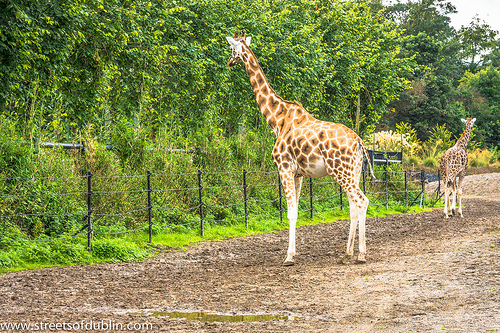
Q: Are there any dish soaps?
A: No, there are no dish soaps.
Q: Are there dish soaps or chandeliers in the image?
A: No, there are no dish soaps or chandeliers.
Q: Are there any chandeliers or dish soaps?
A: No, there are no dish soaps or chandeliers.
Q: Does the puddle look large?
A: Yes, the puddle is large.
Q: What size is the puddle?
A: The puddle is large.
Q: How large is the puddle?
A: The puddle is large.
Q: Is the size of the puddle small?
A: No, the puddle is large.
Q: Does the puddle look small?
A: No, the puddle is large.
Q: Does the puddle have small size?
A: No, the puddle is large.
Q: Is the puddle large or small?
A: The puddle is large.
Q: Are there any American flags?
A: No, there are no American flags.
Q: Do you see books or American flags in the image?
A: No, there are no American flags or books.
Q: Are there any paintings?
A: No, there are no paintings.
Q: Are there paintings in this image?
A: No, there are no paintings.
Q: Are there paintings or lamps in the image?
A: No, there are no paintings or lamps.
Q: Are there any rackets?
A: No, there are no rackets.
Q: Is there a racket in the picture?
A: No, there are no rackets.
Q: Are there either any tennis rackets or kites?
A: No, there are no tennis rackets or kites.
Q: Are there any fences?
A: Yes, there is a fence.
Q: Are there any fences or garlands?
A: Yes, there is a fence.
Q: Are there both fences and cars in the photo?
A: No, there is a fence but no cars.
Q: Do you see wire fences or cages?
A: Yes, there is a wire fence.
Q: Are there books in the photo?
A: No, there are no books.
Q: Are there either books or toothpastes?
A: No, there are no books or toothpastes.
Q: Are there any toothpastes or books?
A: No, there are no books or toothpastes.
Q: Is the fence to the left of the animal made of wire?
A: Yes, the fence is made of wire.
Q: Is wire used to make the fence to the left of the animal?
A: Yes, the fence is made of wire.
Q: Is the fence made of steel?
A: No, the fence is made of wire.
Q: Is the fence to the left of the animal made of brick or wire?
A: The fence is made of wire.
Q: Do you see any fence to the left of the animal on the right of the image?
A: Yes, there is a fence to the left of the animal.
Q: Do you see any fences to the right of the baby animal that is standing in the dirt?
A: No, the fence is to the left of the animal.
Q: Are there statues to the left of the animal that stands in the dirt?
A: No, there is a fence to the left of the animal.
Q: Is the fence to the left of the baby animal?
A: Yes, the fence is to the left of the animal.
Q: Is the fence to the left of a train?
A: No, the fence is to the left of the animal.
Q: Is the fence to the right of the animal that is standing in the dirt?
A: No, the fence is to the left of the animal.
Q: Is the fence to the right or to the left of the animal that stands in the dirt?
A: The fence is to the left of the animal.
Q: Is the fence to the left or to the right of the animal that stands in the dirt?
A: The fence is to the left of the animal.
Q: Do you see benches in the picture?
A: No, there are no benches.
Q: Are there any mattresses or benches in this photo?
A: No, there are no benches or mattresses.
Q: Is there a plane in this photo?
A: No, there are no airplanes.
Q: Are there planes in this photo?
A: No, there are no planes.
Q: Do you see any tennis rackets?
A: No, there are no tennis rackets.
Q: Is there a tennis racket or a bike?
A: No, there are no rackets or bikes.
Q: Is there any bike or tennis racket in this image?
A: No, there are no rackets or bikes.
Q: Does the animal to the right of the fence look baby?
A: Yes, the animal is a baby.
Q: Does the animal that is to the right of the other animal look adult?
A: No, the animal is a baby.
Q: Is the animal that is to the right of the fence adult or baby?
A: The animal is a baby.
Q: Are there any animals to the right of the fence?
A: Yes, there is an animal to the right of the fence.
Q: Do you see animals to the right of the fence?
A: Yes, there is an animal to the right of the fence.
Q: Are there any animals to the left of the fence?
A: No, the animal is to the right of the fence.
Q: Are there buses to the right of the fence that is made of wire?
A: No, there is an animal to the right of the fence.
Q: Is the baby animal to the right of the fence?
A: Yes, the animal is to the right of the fence.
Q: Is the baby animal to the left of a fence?
A: No, the animal is to the right of a fence.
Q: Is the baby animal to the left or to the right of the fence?
A: The animal is to the right of the fence.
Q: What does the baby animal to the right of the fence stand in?
A: The animal stands in the dirt.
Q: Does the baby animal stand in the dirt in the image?
A: Yes, the animal stands in the dirt.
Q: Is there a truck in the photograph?
A: No, there are no trucks.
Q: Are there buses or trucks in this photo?
A: No, there are no trucks or buses.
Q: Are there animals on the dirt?
A: Yes, there is an animal on the dirt.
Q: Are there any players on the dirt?
A: No, there is an animal on the dirt.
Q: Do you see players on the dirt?
A: No, there is an animal on the dirt.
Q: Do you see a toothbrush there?
A: No, there are no toothbrushes.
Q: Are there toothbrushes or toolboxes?
A: No, there are no toothbrushes or toolboxes.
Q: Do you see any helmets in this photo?
A: No, there are no helmets.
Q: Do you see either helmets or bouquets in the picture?
A: No, there are no helmets or bouquets.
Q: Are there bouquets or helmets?
A: No, there are no helmets or bouquets.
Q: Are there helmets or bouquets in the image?
A: No, there are no helmets or bouquets.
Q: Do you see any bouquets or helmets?
A: No, there are no helmets or bouquets.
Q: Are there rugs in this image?
A: No, there are no rugs.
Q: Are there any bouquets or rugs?
A: No, there are no rugs or bouquets.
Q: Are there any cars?
A: No, there are no cars.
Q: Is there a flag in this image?
A: No, there are no flags.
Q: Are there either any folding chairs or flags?
A: No, there are no flags or folding chairs.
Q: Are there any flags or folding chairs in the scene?
A: No, there are no flags or folding chairs.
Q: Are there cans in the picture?
A: No, there are no cans.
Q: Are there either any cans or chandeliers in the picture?
A: No, there are no cans or chandeliers.